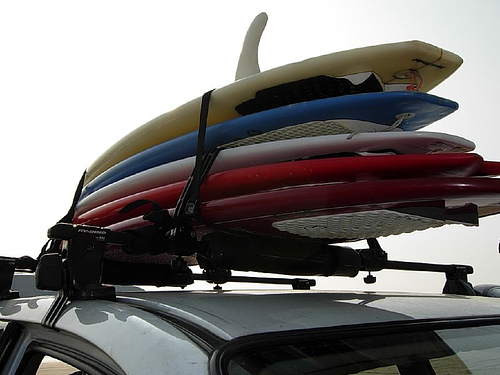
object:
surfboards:
[98, 177, 499, 250]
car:
[0, 289, 500, 375]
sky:
[0, 0, 499, 298]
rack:
[32, 224, 482, 312]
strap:
[194, 87, 216, 201]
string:
[344, 114, 408, 141]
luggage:
[57, 178, 500, 295]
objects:
[74, 154, 500, 233]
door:
[0, 316, 125, 375]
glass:
[221, 320, 499, 375]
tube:
[160, 224, 201, 257]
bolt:
[213, 280, 222, 290]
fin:
[235, 11, 273, 81]